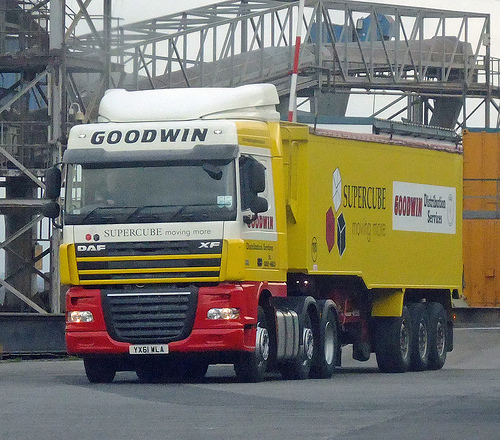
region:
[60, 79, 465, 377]
The truck is yellow.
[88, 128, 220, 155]
The truck's name is Goodwin.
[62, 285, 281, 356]
This part is red.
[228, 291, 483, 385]
One side has 6 tires.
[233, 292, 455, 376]
The tires are black.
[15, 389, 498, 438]
This asphalt is grey.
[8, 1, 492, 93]
The bridge is grey.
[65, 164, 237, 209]
The glass is clear.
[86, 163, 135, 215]
A man is driving.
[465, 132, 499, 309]
The door is yellow.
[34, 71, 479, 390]
truck on the street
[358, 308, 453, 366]
wheels on the truck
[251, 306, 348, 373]
wheels on the truck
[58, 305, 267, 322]
lights on the truck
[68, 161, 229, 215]
window on the truck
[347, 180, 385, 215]
name on the truck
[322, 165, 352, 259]
images on the truck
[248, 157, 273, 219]
mirror on the truck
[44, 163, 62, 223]
mirror on the truck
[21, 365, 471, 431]
street where truck travels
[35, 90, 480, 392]
large yellow and red semi truck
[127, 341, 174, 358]
black and white license plate on the truck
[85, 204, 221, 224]
three black windshield wipers on the truck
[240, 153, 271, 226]
black side view mirror of the truck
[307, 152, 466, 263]
company logos painted on the side of the truck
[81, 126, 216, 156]
black Goodwin painted across the top of the truck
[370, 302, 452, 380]
three large lack tires on the truck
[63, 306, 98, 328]
rectangular headlight on the truck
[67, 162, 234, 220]
large windshield on the truck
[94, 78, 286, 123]
white wind screen on the top of the truck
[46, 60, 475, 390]
The truck is predominantly yellow.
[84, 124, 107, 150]
The letter is black.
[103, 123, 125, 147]
The letter is black.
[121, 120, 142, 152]
The letter is black.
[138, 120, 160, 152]
The letter is black.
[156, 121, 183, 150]
The letter is black.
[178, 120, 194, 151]
The letter is black.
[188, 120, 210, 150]
The letter is black.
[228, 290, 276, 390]
The tire is black.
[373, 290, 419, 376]
The tire is black.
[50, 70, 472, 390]
a big truck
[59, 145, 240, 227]
a windshield of truck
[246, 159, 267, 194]
a side mirror of truck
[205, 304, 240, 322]
lights on truck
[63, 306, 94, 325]
lights on truck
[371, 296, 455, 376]
three wheels of truck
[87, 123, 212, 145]
a print on truck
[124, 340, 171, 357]
a plate number of truck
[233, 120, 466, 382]
a side of the truck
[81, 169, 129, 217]
a driver in the truck